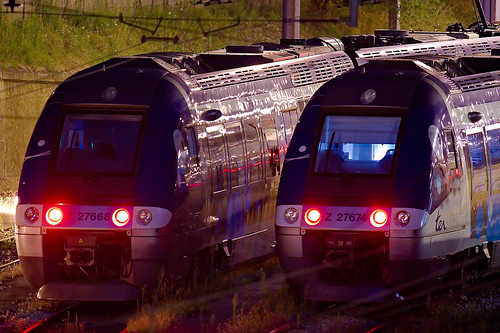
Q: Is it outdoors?
A: Yes, it is outdoors.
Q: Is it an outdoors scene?
A: Yes, it is outdoors.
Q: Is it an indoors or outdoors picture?
A: It is outdoors.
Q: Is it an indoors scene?
A: No, it is outdoors.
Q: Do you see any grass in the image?
A: Yes, there is grass.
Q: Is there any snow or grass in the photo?
A: Yes, there is grass.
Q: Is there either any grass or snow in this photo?
A: Yes, there is grass.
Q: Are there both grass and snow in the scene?
A: No, there is grass but no snow.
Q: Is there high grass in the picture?
A: Yes, there is high grass.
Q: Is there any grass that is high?
A: Yes, there is grass that is high.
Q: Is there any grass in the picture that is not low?
A: Yes, there is high grass.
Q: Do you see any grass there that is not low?
A: Yes, there is high grass.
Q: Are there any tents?
A: No, there are no tents.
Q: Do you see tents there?
A: No, there are no tents.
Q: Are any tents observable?
A: No, there are no tents.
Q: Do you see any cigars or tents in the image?
A: No, there are no tents or cigars.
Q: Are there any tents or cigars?
A: No, there are no tents or cigars.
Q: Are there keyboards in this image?
A: Yes, there is a keyboard.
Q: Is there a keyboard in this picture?
A: Yes, there is a keyboard.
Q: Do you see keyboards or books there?
A: Yes, there is a keyboard.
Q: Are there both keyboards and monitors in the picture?
A: No, there is a keyboard but no monitors.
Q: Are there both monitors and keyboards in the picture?
A: No, there is a keyboard but no monitors.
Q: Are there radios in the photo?
A: No, there are no radios.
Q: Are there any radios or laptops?
A: No, there are no radios or laptops.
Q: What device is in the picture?
A: The device is a keyboard.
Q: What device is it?
A: The device is a keyboard.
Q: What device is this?
A: That is a keyboard.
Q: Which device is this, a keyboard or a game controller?
A: That is a keyboard.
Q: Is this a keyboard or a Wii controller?
A: This is a keyboard.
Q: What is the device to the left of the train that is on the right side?
A: The device is a keyboard.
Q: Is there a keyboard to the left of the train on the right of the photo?
A: Yes, there is a keyboard to the left of the train.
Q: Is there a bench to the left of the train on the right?
A: No, there is a keyboard to the left of the train.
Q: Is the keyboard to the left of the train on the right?
A: Yes, the keyboard is to the left of the train.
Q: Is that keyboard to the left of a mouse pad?
A: No, the keyboard is to the left of the train.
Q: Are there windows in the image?
A: Yes, there are windows.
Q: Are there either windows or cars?
A: Yes, there are windows.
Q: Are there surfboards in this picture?
A: No, there are no surfboards.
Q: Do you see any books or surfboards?
A: No, there are no surfboards or books.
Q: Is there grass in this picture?
A: Yes, there is grass.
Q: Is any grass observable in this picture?
A: Yes, there is grass.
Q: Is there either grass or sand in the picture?
A: Yes, there is grass.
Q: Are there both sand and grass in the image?
A: No, there is grass but no sand.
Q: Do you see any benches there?
A: No, there are no benches.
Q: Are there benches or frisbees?
A: No, there are no benches or frisbees.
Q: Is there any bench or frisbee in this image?
A: No, there are no benches or frisbees.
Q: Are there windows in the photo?
A: Yes, there is a window.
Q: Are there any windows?
A: Yes, there is a window.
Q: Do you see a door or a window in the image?
A: Yes, there is a window.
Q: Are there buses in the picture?
A: No, there are no buses.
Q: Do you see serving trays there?
A: No, there are no serving trays.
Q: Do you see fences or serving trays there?
A: No, there are no serving trays or fences.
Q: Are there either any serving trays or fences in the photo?
A: No, there are no serving trays or fences.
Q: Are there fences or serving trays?
A: No, there are no serving trays or fences.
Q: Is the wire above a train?
A: Yes, the wire is above a train.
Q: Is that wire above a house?
A: No, the wire is above a train.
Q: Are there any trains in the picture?
A: Yes, there is a train.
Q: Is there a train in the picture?
A: Yes, there is a train.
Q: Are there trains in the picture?
A: Yes, there is a train.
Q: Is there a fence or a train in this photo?
A: Yes, there is a train.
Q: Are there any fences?
A: No, there are no fences.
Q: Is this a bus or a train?
A: This is a train.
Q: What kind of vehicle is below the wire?
A: The vehicle is a train.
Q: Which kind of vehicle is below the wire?
A: The vehicle is a train.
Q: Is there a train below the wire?
A: Yes, there is a train below the wire.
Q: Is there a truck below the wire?
A: No, there is a train below the wire.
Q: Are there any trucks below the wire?
A: No, there is a train below the wire.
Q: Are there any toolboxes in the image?
A: No, there are no toolboxes.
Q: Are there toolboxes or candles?
A: No, there are no toolboxes or candles.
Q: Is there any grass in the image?
A: Yes, there is grass.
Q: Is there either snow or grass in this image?
A: Yes, there is grass.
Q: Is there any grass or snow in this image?
A: Yes, there is grass.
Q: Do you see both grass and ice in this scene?
A: No, there is grass but no ice.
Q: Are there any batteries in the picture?
A: No, there are no batteries.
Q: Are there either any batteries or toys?
A: No, there are no batteries or toys.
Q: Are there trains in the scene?
A: Yes, there is a train.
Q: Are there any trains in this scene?
A: Yes, there is a train.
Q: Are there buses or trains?
A: Yes, there is a train.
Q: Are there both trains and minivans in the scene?
A: No, there is a train but no minivans.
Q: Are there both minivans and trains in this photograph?
A: No, there is a train but no minivans.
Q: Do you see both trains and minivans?
A: No, there is a train but no minivans.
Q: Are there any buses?
A: No, there are no buses.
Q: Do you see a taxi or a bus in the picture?
A: No, there are no buses or taxis.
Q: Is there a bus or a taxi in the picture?
A: No, there are no buses or taxis.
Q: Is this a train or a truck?
A: This is a train.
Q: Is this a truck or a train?
A: This is a train.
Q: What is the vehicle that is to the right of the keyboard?
A: The vehicle is a train.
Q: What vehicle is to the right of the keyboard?
A: The vehicle is a train.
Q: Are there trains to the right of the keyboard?
A: Yes, there is a train to the right of the keyboard.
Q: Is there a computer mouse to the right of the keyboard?
A: No, there is a train to the right of the keyboard.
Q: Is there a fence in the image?
A: No, there are no fences.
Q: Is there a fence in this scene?
A: No, there are no fences.